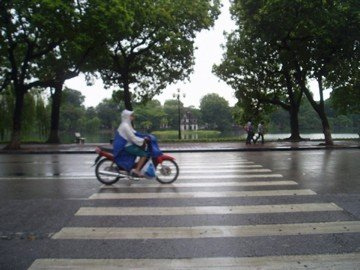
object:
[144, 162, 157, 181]
bag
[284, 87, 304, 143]
tree trunk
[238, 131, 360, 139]
pond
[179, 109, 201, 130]
house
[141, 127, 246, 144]
field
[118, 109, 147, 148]
hoodie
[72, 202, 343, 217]
line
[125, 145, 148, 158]
pants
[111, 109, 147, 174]
rain parka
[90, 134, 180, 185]
bicycle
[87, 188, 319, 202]
stripe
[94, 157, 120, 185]
wheel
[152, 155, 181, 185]
wheel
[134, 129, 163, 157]
tarp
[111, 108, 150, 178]
person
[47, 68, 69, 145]
tree trunk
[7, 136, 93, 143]
grass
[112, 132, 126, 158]
blue tarp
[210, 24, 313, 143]
tree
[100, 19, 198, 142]
tree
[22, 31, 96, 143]
tree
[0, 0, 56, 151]
tree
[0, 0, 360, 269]
background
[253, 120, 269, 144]
people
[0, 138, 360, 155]
sidewalk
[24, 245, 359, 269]
white line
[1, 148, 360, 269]
road